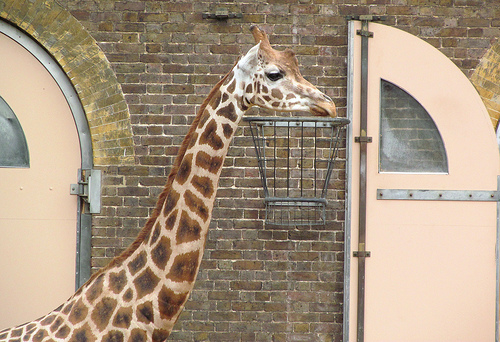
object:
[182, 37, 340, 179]
giraffe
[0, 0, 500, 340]
wall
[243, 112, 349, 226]
basket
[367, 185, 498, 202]
metal strip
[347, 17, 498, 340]
door